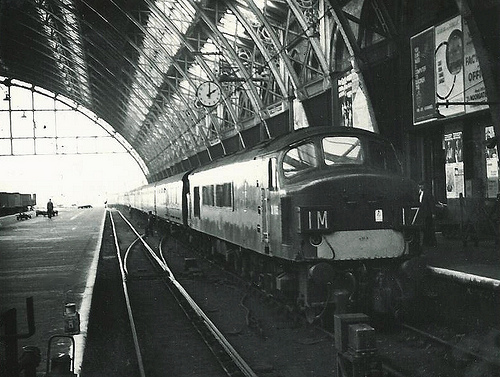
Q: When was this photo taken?
A: During the day.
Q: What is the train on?
A: The tracks.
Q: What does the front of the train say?
A: IM 17.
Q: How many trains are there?
A: One.